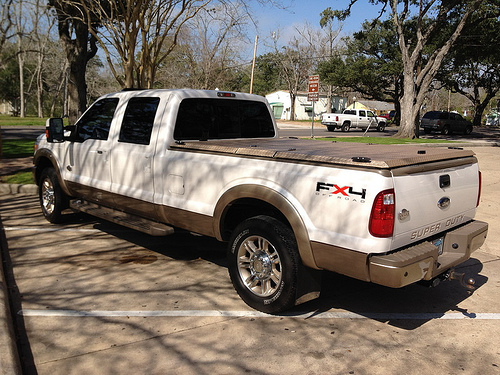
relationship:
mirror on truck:
[43, 114, 68, 143] [31, 86, 490, 317]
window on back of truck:
[171, 94, 275, 140] [31, 86, 490, 317]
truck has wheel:
[13, 60, 489, 318] [222, 214, 304, 317]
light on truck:
[367, 182, 413, 252] [18, 49, 495, 344]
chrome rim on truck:
[240, 234, 280, 296] [31, 86, 490, 317]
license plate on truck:
[429, 238, 445, 253] [31, 86, 490, 317]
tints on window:
[131, 105, 153, 135] [119, 96, 167, 155]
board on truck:
[67, 190, 202, 263] [21, 59, 465, 341]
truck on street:
[317, 106, 394, 135] [293, 121, 396, 143]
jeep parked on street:
[417, 106, 477, 138] [2, 122, 396, 142]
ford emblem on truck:
[438, 194, 453, 210] [31, 86, 490, 317]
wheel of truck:
[222, 206, 304, 311] [37, 46, 488, 315]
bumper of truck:
[384, 221, 499, 303] [31, 86, 490, 317]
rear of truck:
[374, 158, 497, 298] [126, 86, 457, 287]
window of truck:
[117, 92, 160, 146] [31, 86, 490, 317]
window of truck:
[117, 92, 160, 151] [41, 82, 424, 289]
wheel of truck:
[28, 167, 66, 227] [31, 86, 490, 317]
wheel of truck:
[222, 214, 304, 317] [31, 86, 490, 317]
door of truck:
[62, 97, 121, 199] [31, 86, 490, 317]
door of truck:
[109, 92, 169, 229] [31, 86, 490, 317]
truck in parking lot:
[31, 86, 490, 317] [10, 135, 496, 373]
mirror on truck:
[35, 100, 68, 143] [31, 86, 490, 317]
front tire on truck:
[34, 170, 66, 225] [31, 86, 490, 317]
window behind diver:
[117, 92, 160, 146] [40, 82, 485, 313]